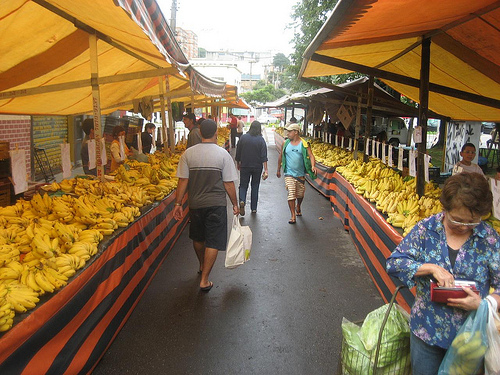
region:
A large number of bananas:
[0, 177, 156, 312]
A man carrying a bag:
[172, 126, 252, 296]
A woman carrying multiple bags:
[364, 184, 499, 369]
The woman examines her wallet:
[415, 259, 475, 304]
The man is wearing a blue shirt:
[285, 142, 308, 176]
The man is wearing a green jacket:
[275, 136, 310, 175]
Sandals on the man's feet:
[192, 269, 212, 293]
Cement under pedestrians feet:
[238, 227, 320, 370]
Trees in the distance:
[293, 3, 321, 78]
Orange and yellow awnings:
[324, 13, 492, 116]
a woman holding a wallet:
[386, 171, 497, 373]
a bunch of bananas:
[18, 264, 57, 293]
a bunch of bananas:
[49, 251, 84, 279]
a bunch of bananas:
[63, 239, 93, 259]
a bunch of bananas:
[88, 221, 116, 233]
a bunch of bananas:
[105, 211, 127, 224]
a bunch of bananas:
[49, 199, 71, 220]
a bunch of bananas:
[26, 191, 48, 213]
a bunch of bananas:
[392, 194, 413, 214]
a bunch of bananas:
[363, 179, 378, 199]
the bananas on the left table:
[15, 197, 95, 254]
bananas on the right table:
[347, 162, 385, 190]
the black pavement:
[265, 245, 338, 355]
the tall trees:
[273, 1, 325, 95]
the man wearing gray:
[172, 117, 248, 292]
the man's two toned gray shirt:
[177, 142, 237, 209]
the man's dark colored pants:
[186, 201, 232, 251]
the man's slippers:
[192, 264, 212, 290]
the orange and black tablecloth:
[44, 255, 142, 362]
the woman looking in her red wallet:
[387, 168, 498, 373]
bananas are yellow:
[37, 185, 155, 239]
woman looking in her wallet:
[418, 273, 498, 313]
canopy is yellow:
[339, 29, 497, 122]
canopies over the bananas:
[49, 30, 236, 104]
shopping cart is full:
[349, 285, 431, 374]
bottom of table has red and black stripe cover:
[63, 287, 126, 360]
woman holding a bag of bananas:
[450, 315, 490, 372]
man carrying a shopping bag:
[232, 192, 259, 272]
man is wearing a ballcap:
[275, 117, 316, 137]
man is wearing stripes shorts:
[277, 168, 322, 204]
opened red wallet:
[428, 273, 483, 302]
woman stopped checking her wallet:
[342, 165, 499, 370]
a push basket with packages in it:
[346, 260, 418, 371]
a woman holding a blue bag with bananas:
[436, 298, 486, 373]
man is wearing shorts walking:
[170, 112, 257, 294]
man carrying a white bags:
[173, 122, 258, 299]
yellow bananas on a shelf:
[342, 155, 382, 192]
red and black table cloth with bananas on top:
[12, 192, 182, 371]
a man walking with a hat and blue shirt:
[276, 123, 320, 230]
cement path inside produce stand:
[118, 217, 380, 367]